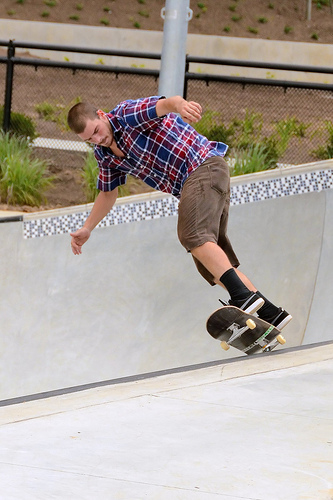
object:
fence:
[0, 37, 333, 171]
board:
[206, 303, 286, 365]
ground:
[0, 342, 333, 500]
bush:
[270, 109, 306, 148]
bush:
[34, 100, 62, 122]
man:
[66, 93, 290, 339]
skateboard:
[205, 304, 287, 358]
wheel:
[221, 338, 231, 352]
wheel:
[244, 317, 258, 330]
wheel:
[270, 330, 285, 345]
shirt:
[96, 93, 230, 197]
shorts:
[175, 149, 238, 286]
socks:
[220, 263, 250, 310]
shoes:
[223, 284, 267, 321]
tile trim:
[23, 166, 333, 244]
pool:
[0, 156, 333, 500]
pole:
[158, 1, 191, 107]